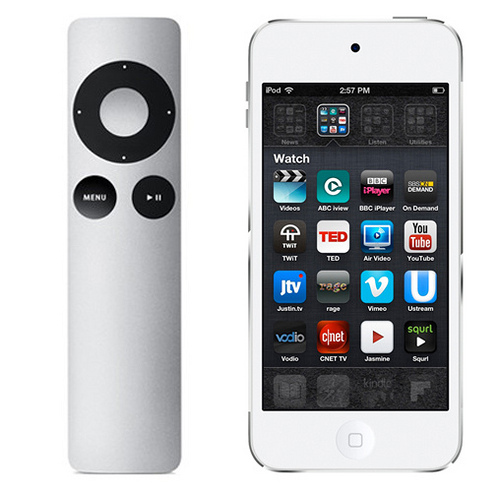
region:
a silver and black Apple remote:
[66, 16, 181, 473]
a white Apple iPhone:
[244, 17, 466, 475]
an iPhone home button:
[334, 418, 374, 461]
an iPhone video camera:
[349, 41, 361, 53]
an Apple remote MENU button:
[72, 174, 118, 220]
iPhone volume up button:
[244, 79, 249, 101]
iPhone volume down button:
[244, 104, 251, 125]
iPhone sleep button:
[393, 14, 428, 19]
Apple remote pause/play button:
[132, 174, 176, 218]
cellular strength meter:
[282, 84, 293, 94]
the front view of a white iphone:
[241, 11, 469, 471]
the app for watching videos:
[275, 162, 305, 200]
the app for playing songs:
[308, 175, 359, 210]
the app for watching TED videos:
[315, 213, 349, 254]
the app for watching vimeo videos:
[352, 256, 399, 310]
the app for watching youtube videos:
[364, 319, 398, 353]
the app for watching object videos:
[320, 323, 347, 353]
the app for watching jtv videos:
[280, 276, 312, 306]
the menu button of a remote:
[70, 171, 120, 225]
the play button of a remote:
[130, 179, 171, 221]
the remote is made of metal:
[57, 13, 189, 478]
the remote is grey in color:
[65, 16, 184, 478]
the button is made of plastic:
[135, 175, 174, 220]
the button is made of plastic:
[73, 175, 111, 217]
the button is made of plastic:
[71, 61, 176, 162]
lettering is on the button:
[82, 190, 109, 205]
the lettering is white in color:
[81, 190, 108, 203]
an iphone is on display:
[245, 17, 465, 467]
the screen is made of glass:
[261, 82, 448, 409]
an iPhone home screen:
[261, 81, 449, 411]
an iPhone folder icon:
[314, 102, 351, 139]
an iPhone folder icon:
[271, 101, 306, 134]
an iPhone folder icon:
[400, 100, 431, 135]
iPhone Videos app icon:
[270, 165, 305, 200]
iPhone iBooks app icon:
[270, 370, 305, 405]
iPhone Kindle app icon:
[355, 370, 390, 405]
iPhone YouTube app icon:
[400, 213, 440, 254]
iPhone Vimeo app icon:
[358, 267, 394, 307]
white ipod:
[208, 26, 496, 493]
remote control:
[50, 17, 210, 485]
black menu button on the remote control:
[71, 173, 125, 226]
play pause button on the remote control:
[130, 174, 185, 229]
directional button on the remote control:
[74, 53, 178, 173]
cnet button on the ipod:
[307, 316, 354, 367]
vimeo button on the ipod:
[356, 265, 398, 315]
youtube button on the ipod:
[393, 218, 443, 271]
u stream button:
[398, 260, 443, 314]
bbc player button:
[353, 158, 407, 211]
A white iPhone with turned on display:
[242, 13, 462, 475]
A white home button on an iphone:
[336, 420, 368, 450]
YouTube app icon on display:
[400, 215, 435, 260]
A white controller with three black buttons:
[65, 15, 180, 475]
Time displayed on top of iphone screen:
[332, 82, 367, 92]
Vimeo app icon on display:
[360, 266, 391, 307]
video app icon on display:
[270, 166, 305, 208]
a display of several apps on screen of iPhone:
[266, 152, 443, 364]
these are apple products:
[57, 18, 418, 462]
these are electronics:
[47, 24, 422, 395]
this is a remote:
[34, 8, 191, 310]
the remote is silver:
[51, 41, 196, 271]